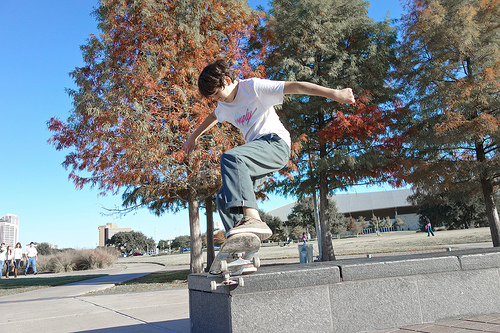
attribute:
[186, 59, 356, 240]
boy — skateboarding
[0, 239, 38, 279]
people — walking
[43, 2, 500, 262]
trees — red, dark green, orange, green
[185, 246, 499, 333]
wall — concrete, grey, stone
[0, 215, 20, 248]
buildings — tall, white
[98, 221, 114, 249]
buildings — white, tall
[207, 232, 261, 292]
skateboard — grey, white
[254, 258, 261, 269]
wheel — white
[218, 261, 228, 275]
wheel — white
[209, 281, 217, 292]
wheel — white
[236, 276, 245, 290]
wheel — white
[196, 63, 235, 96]
hair — brown, black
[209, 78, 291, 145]
shirt — short sleeved, white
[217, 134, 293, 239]
pants — blue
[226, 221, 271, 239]
shoes — grey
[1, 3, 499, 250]
sky — blue, clear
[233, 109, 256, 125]
lettering — pink